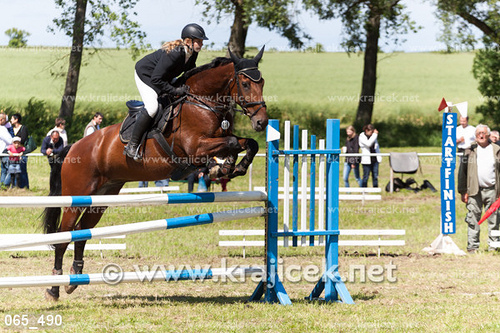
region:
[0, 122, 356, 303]
a blue and white horse hurdle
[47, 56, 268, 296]
a dark brown horse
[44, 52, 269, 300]
a brown horse jumping over a hurdle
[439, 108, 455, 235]
a square pole reading StartFinish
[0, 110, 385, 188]
spectators in the crowd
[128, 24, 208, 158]
woman with black coat on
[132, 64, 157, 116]
a pair of white tight riding pants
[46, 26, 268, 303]
woman riding a horse over a hurdle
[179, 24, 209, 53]
small black helmet with chin strap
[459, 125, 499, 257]
elderly man standing next to finish line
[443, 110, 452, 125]
white letter on sign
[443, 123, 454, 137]
white letter on sign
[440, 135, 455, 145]
white letter on sign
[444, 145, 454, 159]
white letter on sign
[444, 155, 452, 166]
white letter on sign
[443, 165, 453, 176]
white letter on sign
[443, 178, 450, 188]
white letter on sign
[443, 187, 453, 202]
white letter on sign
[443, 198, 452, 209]
white letter on sign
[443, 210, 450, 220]
white letter on sign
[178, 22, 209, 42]
rider wearing a black helmet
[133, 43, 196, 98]
rider wearing a black jacket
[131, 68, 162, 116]
white pants on the rider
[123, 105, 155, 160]
black boots on the rider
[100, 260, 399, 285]
clear watermark logo on the photo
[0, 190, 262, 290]
blue and white jumping bars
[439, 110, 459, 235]
blue and white start/finish sign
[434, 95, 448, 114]
small red flag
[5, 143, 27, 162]
kid wearing a red shirt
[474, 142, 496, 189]
man wearing a white shirt under his coat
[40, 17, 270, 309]
a woman jumping a horse over an obstacle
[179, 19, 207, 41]
a woman with a black helmet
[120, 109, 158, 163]
a woman with black boots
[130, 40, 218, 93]
a woman with a black coat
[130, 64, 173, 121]
a woman with white shoes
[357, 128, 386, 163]
a woman with a white coat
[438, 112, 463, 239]
a sign with the word Start and finish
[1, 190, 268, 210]
a white and blue pole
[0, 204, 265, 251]
a white and blue pole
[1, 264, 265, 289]
a white and blue pole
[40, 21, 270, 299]
horse and rider making a jump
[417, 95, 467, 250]
start/finish sign in white on blue background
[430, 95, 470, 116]
two small flags on top of the start/finish sign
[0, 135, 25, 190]
child in white hat and red top watching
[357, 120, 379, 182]
person in white jacket with hand by face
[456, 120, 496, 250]
older man in white top near finish marker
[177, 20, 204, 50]
black helmet worn by rider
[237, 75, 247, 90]
eye of the jumping horse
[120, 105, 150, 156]
black boot worn by rider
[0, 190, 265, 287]
the rails the horse is jumping over